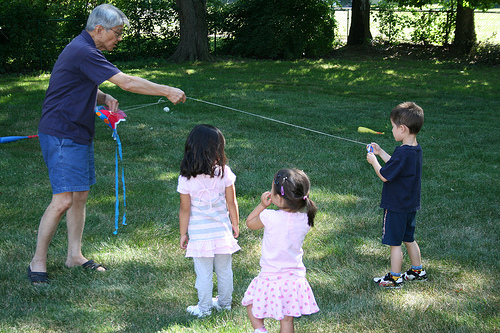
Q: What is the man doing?
A: Playing.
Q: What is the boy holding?
A: String.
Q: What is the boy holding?
A: Kite.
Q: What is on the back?
A: Trees.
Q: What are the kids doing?
A: Playing.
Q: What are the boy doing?
A: Standing.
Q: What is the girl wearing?
A: Skirt.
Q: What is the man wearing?
A: Glasses.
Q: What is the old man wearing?
A: Denim shorts.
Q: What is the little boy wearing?
A: A dark blue shirt and shorts.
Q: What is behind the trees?
A: A chain link fence.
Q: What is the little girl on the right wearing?
A: A white shirt and a pink and white polka dot skirt.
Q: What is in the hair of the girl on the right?
A: A barrette and a ponytail holder.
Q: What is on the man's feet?
A: Sandals.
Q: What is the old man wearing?
A: A dark blue shirt and denim shorts.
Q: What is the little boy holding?
A: A thin light blue string.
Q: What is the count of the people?
A: Four.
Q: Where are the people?
A: People are in the park.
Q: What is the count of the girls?
A: Two.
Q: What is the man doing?
A: Playing with three kids.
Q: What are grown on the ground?
A: Green grass.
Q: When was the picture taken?
A: During the day.